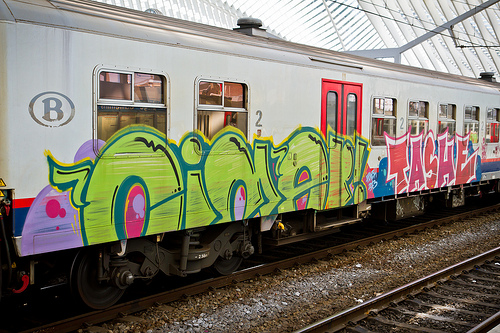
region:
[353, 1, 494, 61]
metal frame and wires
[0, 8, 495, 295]
side of commuter train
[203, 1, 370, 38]
sun light through ceiling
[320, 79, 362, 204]
two red train doors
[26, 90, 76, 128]
letter b in oval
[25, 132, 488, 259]
graffiti on side of train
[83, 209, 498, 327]
two sets of trains tracks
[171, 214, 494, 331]
gravel in between tracks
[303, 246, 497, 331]
metal rail of track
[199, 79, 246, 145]
light reflection on train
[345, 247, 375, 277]
part of a ground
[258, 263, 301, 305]
part of a ground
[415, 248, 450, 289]
part of a rail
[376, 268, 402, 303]
edge of a rail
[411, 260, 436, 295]
edge of a rail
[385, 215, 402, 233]
part of a rail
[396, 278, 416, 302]
edge of a rail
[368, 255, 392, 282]
part of a ground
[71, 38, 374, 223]
this is a train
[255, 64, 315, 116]
the train is white in color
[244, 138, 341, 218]
the train is caligraphed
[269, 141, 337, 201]
the caligraph is green in color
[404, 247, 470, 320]
these are the rails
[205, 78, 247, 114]
this is the window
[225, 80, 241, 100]
the window is open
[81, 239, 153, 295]
this is the wheel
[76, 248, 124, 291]
the wheel is metallic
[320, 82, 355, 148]
this is the door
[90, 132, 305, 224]
Big green graffiti letters on side of train.